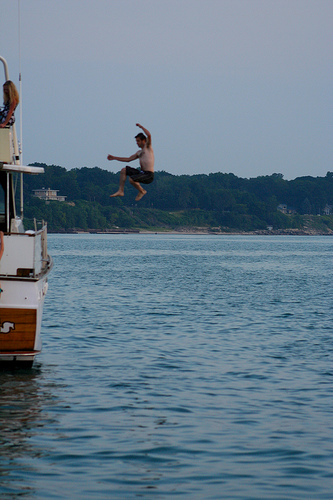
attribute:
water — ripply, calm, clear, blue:
[0, 228, 329, 500]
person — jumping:
[106, 126, 159, 201]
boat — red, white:
[1, 58, 56, 366]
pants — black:
[124, 163, 156, 190]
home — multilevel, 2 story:
[35, 184, 68, 205]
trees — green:
[12, 164, 330, 237]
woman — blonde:
[5, 76, 23, 127]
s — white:
[3, 318, 19, 339]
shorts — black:
[127, 167, 152, 185]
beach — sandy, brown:
[73, 221, 225, 235]